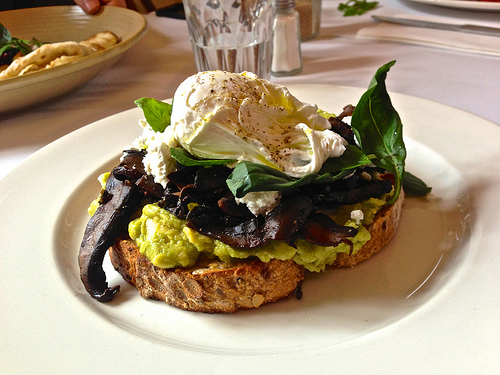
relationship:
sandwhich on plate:
[76, 57, 436, 330] [0, 83, 499, 374]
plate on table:
[6, 84, 495, 369] [9, 19, 493, 136]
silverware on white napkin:
[372, 11, 497, 41] [350, 5, 499, 57]